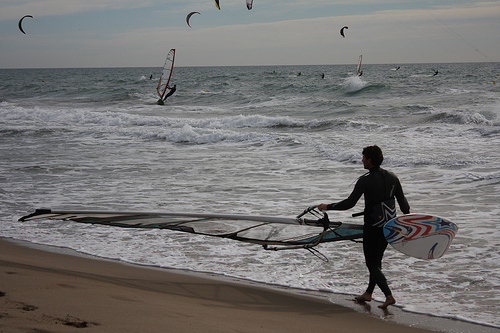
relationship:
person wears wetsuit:
[328, 154, 401, 308] [349, 143, 401, 299]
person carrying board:
[328, 154, 401, 308] [375, 210, 462, 267]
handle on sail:
[299, 198, 330, 226] [40, 207, 388, 260]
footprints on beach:
[12, 267, 138, 306] [6, 240, 356, 326]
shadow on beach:
[37, 269, 325, 319] [6, 240, 356, 326]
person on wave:
[356, 72, 364, 78] [344, 67, 375, 106]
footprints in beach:
[12, 267, 138, 306] [6, 240, 356, 326]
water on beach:
[337, 298, 475, 331] [0, 240, 421, 332]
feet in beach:
[348, 296, 384, 311] [0, 240, 421, 332]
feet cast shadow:
[348, 296, 384, 311] [356, 301, 388, 318]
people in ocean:
[142, 51, 446, 113] [6, 67, 497, 322]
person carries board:
[328, 154, 401, 308] [375, 210, 462, 267]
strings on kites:
[183, 15, 355, 84] [22, 9, 353, 49]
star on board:
[433, 221, 454, 234] [375, 210, 462, 267]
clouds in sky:
[183, 12, 491, 61] [14, 3, 218, 39]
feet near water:
[348, 296, 384, 311] [337, 298, 475, 331]